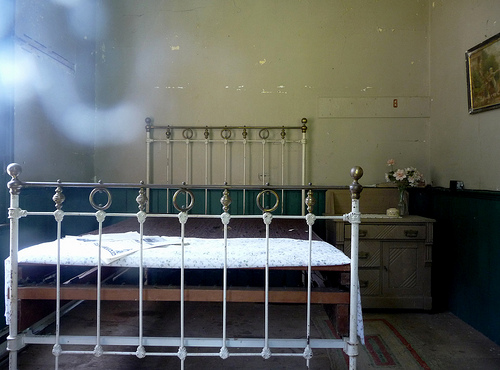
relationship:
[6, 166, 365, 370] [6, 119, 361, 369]
foot of a metal bed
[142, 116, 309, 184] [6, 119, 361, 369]
headboard of bed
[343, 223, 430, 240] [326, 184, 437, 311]
drawer of stand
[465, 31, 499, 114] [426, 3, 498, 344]
painting on wall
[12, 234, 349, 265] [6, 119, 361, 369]
mattress of bed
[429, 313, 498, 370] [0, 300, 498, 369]
part of carpet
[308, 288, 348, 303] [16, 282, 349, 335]
part of a stand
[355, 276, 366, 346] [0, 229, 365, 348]
edge of a sheet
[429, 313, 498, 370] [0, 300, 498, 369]
part of a carpet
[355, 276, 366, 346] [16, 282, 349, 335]
edge of a stand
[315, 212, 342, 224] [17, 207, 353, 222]
part of a metal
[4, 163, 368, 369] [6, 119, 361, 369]
footboard of bed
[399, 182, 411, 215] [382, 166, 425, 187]
bottle holding flowers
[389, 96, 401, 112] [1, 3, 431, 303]
8 on wall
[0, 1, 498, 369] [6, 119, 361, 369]
bedroom with bed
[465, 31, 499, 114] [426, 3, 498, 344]
painting hanging on wall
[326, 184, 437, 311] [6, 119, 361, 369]
stand near bed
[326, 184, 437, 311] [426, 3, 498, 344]
stand near wall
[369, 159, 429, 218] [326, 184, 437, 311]
flower above stand